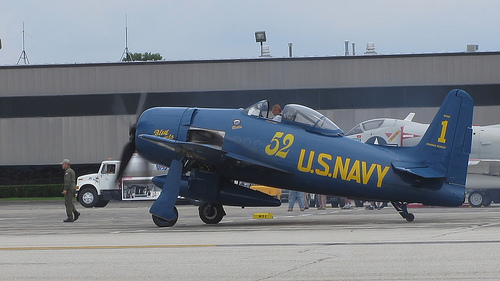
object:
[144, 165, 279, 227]
landing gear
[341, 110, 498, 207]
plane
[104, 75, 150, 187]
propeller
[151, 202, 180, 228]
front wheel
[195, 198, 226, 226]
front wheel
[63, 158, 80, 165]
cap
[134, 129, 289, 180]
wing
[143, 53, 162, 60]
leaves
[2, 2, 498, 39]
background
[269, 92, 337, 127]
glass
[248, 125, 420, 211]
writing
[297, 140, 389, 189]
signage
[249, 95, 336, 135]
cockpit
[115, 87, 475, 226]
aircraft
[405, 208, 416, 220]
wheel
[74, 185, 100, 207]
wheel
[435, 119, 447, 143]
writing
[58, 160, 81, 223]
man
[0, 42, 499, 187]
building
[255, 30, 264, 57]
flag light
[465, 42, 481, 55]
light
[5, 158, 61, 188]
windows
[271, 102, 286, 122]
man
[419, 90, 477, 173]
tail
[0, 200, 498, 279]
airstrip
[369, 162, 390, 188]
letters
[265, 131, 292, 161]
number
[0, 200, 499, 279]
runway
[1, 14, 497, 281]
airport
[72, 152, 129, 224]
vehicle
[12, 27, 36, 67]
antenna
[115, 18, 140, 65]
antenna